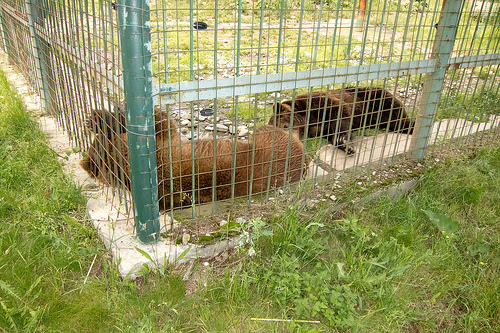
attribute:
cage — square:
[1, 0, 496, 280]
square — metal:
[228, 141, 257, 172]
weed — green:
[259, 245, 306, 313]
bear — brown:
[79, 98, 304, 208]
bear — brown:
[85, 100, 327, 207]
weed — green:
[274, 238, 325, 299]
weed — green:
[234, 233, 289, 291]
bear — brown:
[72, 91, 296, 204]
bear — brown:
[83, 89, 322, 193]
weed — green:
[324, 213, 374, 251]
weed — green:
[344, 245, 391, 299]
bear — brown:
[99, 69, 304, 198]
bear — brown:
[63, 95, 313, 202]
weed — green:
[398, 205, 444, 260]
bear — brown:
[75, 92, 298, 184]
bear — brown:
[76, 105, 306, 194]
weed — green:
[407, 202, 448, 257]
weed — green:
[417, 185, 457, 249]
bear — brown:
[68, 79, 315, 214]